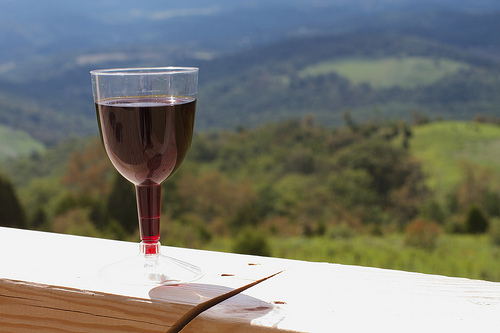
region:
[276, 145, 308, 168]
bunch of trees in the background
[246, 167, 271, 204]
bunch of trees in the background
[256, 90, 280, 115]
bunch of trees in the background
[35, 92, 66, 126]
bunch of trees in the background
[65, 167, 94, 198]
bunch of trees in the background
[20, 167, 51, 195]
bunch of trees in the background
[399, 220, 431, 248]
bunch of trees in the background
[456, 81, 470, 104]
bunch of trees in the background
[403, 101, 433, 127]
bunch of trees in the background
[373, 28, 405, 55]
bunch of trees in the background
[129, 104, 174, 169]
this is a glass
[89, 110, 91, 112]
this is a glass of wine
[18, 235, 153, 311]
this is a sill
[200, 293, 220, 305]
this is a crack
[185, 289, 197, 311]
the crack is long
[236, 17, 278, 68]
this is a mountain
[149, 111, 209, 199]
the wine is red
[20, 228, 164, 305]
there are no people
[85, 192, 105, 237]
there are no animals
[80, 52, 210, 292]
a cup of wine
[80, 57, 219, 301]
the cup is plastic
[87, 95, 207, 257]
the wine is black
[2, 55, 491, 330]
wine on wood surface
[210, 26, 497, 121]
hill covered with vegetation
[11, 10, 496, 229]
trees behind a cup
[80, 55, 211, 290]
cup is almost full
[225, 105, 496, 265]
green hills on a hill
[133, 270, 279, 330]
shadow on wood surface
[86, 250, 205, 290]
base of cup is plastic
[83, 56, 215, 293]
wine is color red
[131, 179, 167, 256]
the handle of cup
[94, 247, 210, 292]
the base of cup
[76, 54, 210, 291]
cup is color white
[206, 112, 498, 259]
trees on a hill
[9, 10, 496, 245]
hills behind a cup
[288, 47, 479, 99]
area covered with grass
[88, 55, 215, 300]
A glass of redwine